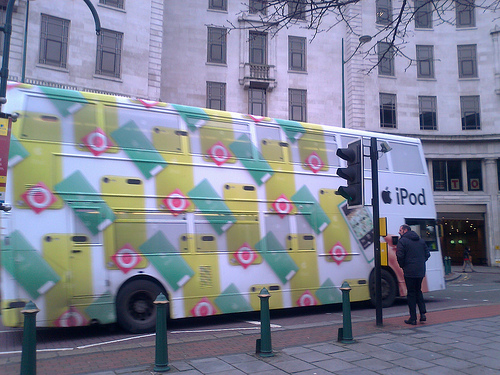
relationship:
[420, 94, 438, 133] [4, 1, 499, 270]
window on building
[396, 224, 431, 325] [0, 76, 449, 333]
man beside bus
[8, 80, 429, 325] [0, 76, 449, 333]
artwork on bus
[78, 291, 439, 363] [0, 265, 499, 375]
pillars on gray road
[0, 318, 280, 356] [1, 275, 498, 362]
line on street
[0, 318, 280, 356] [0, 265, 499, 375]
line on gray road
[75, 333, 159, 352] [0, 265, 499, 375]
line on gray road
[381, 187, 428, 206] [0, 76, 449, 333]
ipod logo on bus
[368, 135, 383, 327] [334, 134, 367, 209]
pole attached to traffic signal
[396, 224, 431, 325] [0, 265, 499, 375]
man next to gray road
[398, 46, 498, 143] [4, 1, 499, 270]
window on building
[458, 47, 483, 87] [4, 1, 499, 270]
window on building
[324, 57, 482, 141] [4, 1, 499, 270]
window on building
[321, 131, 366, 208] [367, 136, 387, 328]
sign on pole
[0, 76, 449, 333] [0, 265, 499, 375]
bus on gray road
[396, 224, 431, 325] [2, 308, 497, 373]
man on sidewalk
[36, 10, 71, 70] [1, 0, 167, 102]
window on building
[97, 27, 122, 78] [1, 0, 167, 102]
window on building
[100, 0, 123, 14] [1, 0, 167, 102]
window on building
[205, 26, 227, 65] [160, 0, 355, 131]
window on building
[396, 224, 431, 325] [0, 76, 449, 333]
man on bus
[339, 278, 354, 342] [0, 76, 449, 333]
post on bus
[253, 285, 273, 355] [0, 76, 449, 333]
post on bus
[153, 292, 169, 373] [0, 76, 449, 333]
pillars on bus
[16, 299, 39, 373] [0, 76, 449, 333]
post on bus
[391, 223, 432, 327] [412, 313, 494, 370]
man on concrete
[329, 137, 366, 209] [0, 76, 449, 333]
traffic signal near bus